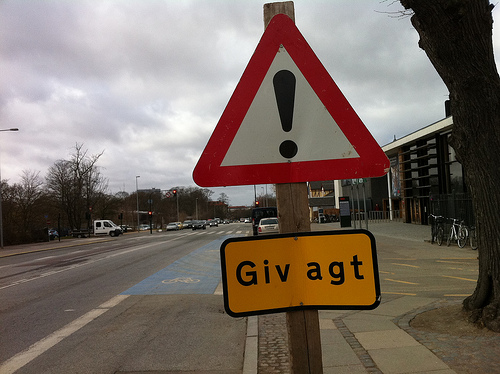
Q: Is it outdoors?
A: Yes, it is outdoors.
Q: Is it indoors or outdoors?
A: It is outdoors.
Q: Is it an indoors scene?
A: No, it is outdoors.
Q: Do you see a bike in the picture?
A: Yes, there is a bike.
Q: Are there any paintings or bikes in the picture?
A: Yes, there is a bike.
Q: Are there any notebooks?
A: No, there are no notebooks.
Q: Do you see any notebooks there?
A: No, there are no notebooks.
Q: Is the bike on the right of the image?
A: Yes, the bike is on the right of the image.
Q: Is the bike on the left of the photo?
A: No, the bike is on the right of the image.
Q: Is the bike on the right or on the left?
A: The bike is on the right of the image.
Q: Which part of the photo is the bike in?
A: The bike is on the right of the image.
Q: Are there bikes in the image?
A: Yes, there is a bike.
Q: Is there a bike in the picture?
A: Yes, there is a bike.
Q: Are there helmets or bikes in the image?
A: Yes, there is a bike.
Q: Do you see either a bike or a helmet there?
A: Yes, there is a bike.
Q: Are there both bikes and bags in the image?
A: No, there is a bike but no bags.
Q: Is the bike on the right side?
A: Yes, the bike is on the right of the image.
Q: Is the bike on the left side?
A: No, the bike is on the right of the image.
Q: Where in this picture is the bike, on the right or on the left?
A: The bike is on the right of the image.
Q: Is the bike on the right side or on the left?
A: The bike is on the right of the image.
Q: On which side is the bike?
A: The bike is on the right of the image.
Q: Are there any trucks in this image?
A: Yes, there is a truck.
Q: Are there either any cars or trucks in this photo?
A: Yes, there is a truck.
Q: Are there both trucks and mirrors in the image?
A: No, there is a truck but no mirrors.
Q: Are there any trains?
A: No, there are no trains.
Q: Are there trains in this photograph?
A: No, there are no trains.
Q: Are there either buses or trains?
A: No, there are no trains or buses.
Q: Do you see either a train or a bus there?
A: No, there are no trains or buses.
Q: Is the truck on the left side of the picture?
A: Yes, the truck is on the left of the image.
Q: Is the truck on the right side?
A: No, the truck is on the left of the image.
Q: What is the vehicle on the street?
A: The vehicle is a truck.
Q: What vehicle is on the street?
A: The vehicle is a truck.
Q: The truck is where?
A: The truck is on the street.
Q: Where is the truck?
A: The truck is on the street.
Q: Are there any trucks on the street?
A: Yes, there is a truck on the street.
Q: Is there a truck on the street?
A: Yes, there is a truck on the street.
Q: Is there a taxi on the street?
A: No, there is a truck on the street.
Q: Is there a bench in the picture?
A: No, there are no benches.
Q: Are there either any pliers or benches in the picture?
A: No, there are no benches or pliers.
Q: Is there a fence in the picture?
A: No, there are no fences.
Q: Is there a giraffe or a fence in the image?
A: No, there are no fences or giraffes.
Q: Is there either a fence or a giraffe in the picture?
A: No, there are no fences or giraffes.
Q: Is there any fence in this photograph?
A: No, there are no fences.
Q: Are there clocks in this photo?
A: No, there are no clocks.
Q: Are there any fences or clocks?
A: No, there are no clocks or fences.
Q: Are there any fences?
A: No, there are no fences.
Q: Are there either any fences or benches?
A: No, there are no fences or benches.